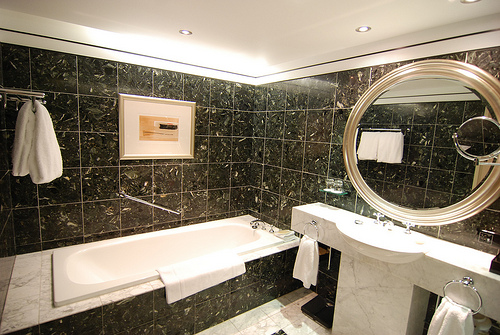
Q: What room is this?
A: It is a bathroom.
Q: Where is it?
A: This is at the bathroom.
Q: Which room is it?
A: It is a bathroom.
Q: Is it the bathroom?
A: Yes, it is the bathroom.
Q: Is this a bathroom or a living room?
A: It is a bathroom.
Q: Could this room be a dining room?
A: No, it is a bathroom.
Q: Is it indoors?
A: Yes, it is indoors.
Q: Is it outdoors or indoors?
A: It is indoors.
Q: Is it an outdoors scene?
A: No, it is indoors.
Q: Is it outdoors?
A: No, it is indoors.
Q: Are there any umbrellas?
A: No, there are no umbrellas.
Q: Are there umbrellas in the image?
A: No, there are no umbrellas.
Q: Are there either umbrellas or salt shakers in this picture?
A: No, there are no umbrellas or salt shakers.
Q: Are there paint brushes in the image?
A: No, there are no paint brushes.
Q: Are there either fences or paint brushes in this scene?
A: No, there are no paint brushes or fences.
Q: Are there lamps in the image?
A: No, there are no lamps.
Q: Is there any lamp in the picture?
A: No, there are no lamps.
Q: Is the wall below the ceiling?
A: Yes, the wall is below the ceiling.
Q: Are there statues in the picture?
A: No, there are no statues.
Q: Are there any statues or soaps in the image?
A: No, there are no statues or soaps.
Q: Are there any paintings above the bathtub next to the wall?
A: Yes, there is a painting above the bath tub.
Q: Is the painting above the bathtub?
A: Yes, the painting is above the bathtub.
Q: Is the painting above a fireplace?
A: No, the painting is above the bathtub.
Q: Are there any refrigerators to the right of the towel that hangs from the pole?
A: No, there is a painting to the right of the towel.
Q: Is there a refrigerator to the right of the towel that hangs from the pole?
A: No, there is a painting to the right of the towel.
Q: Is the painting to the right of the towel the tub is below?
A: Yes, the painting is to the right of the towel.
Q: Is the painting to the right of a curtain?
A: No, the painting is to the right of the towel.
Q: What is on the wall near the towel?
A: The painting is on the wall.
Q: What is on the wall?
A: The painting is on the wall.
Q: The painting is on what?
A: The painting is on the wall.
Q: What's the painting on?
A: The painting is on the wall.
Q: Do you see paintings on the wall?
A: Yes, there is a painting on the wall.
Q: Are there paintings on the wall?
A: Yes, there is a painting on the wall.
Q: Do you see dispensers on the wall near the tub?
A: No, there is a painting on the wall.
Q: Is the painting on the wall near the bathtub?
A: Yes, the painting is on the wall.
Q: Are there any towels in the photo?
A: Yes, there is a towel.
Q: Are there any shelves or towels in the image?
A: Yes, there is a towel.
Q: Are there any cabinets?
A: No, there are no cabinets.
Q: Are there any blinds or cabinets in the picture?
A: No, there are no cabinets or blinds.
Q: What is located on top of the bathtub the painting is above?
A: The towel is on top of the bathtub.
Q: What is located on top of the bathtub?
A: The towel is on top of the bathtub.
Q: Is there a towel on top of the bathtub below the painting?
A: Yes, there is a towel on top of the tub.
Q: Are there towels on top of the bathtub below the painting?
A: Yes, there is a towel on top of the tub.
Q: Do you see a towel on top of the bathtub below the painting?
A: Yes, there is a towel on top of the tub.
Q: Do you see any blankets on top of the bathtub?
A: No, there is a towel on top of the bathtub.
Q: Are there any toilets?
A: No, there are no toilets.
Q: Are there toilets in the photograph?
A: No, there are no toilets.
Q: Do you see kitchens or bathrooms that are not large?
A: No, there is a bathroom but it is large.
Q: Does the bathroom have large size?
A: Yes, the bathroom is large.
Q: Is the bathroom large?
A: Yes, the bathroom is large.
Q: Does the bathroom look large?
A: Yes, the bathroom is large.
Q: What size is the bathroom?
A: The bathroom is large.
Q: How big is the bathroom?
A: The bathroom is large.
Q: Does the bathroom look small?
A: No, the bathroom is large.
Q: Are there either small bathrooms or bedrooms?
A: No, there is a bathroom but it is large.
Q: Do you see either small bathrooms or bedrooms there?
A: No, there is a bathroom but it is large.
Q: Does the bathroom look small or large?
A: The bathroom is large.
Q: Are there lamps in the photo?
A: No, there are no lamps.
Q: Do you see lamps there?
A: No, there are no lamps.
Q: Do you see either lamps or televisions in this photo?
A: No, there are no lamps or televisions.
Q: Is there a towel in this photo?
A: Yes, there is a towel.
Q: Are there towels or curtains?
A: Yes, there is a towel.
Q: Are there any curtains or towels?
A: Yes, there is a towel.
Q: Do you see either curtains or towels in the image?
A: Yes, there is a towel.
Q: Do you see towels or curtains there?
A: Yes, there is a towel.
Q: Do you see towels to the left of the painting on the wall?
A: Yes, there is a towel to the left of the painting.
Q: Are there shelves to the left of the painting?
A: No, there is a towel to the left of the painting.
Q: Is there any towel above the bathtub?
A: Yes, there is a towel above the bathtub.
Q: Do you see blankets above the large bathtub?
A: No, there is a towel above the bathtub.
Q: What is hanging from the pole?
A: The towel is hanging from the pole.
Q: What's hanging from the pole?
A: The towel is hanging from the pole.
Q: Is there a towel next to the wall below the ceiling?
A: Yes, there is a towel next to the wall.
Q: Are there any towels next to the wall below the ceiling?
A: Yes, there is a towel next to the wall.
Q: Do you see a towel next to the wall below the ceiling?
A: Yes, there is a towel next to the wall.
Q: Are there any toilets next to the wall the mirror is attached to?
A: No, there is a towel next to the wall.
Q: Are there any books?
A: No, there are no books.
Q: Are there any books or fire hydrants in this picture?
A: No, there are no books or fire hydrants.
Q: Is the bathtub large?
A: Yes, the bathtub is large.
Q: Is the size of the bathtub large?
A: Yes, the bathtub is large.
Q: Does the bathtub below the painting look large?
A: Yes, the bathtub is large.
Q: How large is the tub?
A: The tub is large.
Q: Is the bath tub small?
A: No, the bath tub is large.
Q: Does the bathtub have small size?
A: No, the bathtub is large.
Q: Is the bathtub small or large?
A: The bathtub is large.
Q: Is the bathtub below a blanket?
A: No, the bathtub is below a towel.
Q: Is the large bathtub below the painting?
A: Yes, the bathtub is below the painting.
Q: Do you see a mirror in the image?
A: Yes, there is a mirror.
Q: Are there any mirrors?
A: Yes, there is a mirror.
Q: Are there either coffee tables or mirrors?
A: Yes, there is a mirror.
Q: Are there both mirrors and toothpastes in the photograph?
A: No, there is a mirror but no toothpastes.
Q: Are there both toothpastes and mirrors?
A: No, there is a mirror but no toothpastes.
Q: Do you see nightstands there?
A: No, there are no nightstands.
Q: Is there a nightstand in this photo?
A: No, there are no nightstands.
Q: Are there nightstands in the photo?
A: No, there are no nightstands.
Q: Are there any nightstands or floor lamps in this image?
A: No, there are no nightstands or floor lamps.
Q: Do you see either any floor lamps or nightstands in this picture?
A: No, there are no nightstands or floor lamps.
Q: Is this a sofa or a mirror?
A: This is a mirror.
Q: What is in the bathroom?
A: The mirror is in the bathroom.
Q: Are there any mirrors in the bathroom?
A: Yes, there is a mirror in the bathroom.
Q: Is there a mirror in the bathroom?
A: Yes, there is a mirror in the bathroom.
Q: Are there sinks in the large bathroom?
A: No, there is a mirror in the bathroom.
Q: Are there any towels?
A: Yes, there is a towel.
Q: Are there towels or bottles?
A: Yes, there is a towel.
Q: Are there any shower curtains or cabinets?
A: No, there are no cabinets or shower curtains.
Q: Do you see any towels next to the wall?
A: Yes, there is a towel next to the wall.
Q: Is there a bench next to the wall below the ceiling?
A: No, there is a towel next to the wall.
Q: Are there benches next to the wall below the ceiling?
A: No, there is a towel next to the wall.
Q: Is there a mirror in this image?
A: Yes, there is a mirror.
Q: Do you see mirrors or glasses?
A: Yes, there is a mirror.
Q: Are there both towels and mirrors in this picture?
A: Yes, there are both a mirror and a towel.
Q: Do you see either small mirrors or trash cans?
A: Yes, there is a small mirror.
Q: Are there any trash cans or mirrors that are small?
A: Yes, the mirror is small.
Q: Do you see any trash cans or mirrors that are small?
A: Yes, the mirror is small.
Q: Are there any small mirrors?
A: Yes, there is a small mirror.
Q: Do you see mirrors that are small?
A: Yes, there is a mirror that is small.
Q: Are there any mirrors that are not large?
A: Yes, there is a small mirror.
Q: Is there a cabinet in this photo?
A: No, there are no cabinets.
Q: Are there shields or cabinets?
A: No, there are no cabinets or shields.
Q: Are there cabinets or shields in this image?
A: No, there are no cabinets or shields.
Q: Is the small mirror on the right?
A: Yes, the mirror is on the right of the image.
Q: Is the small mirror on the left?
A: No, the mirror is on the right of the image.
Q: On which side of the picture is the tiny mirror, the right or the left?
A: The mirror is on the right of the image.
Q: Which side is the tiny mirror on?
A: The mirror is on the right of the image.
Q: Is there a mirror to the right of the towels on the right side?
A: Yes, there is a mirror to the right of the towels.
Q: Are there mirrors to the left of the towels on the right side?
A: No, the mirror is to the right of the towels.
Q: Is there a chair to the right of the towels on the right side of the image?
A: No, there is a mirror to the right of the towels.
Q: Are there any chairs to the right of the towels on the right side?
A: No, there is a mirror to the right of the towels.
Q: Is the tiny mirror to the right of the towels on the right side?
A: Yes, the mirror is to the right of the towels.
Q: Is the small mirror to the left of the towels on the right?
A: No, the mirror is to the right of the towels.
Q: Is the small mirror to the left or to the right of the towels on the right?
A: The mirror is to the right of the towels.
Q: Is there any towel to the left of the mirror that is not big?
A: Yes, there are towels to the left of the mirror.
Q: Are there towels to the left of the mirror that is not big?
A: Yes, there are towels to the left of the mirror.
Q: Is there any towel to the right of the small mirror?
A: No, the towels are to the left of the mirror.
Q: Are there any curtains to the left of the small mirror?
A: No, there are towels to the left of the mirror.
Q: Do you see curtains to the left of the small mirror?
A: No, there are towels to the left of the mirror.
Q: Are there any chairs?
A: No, there are no chairs.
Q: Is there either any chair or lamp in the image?
A: No, there are no chairs or lamps.